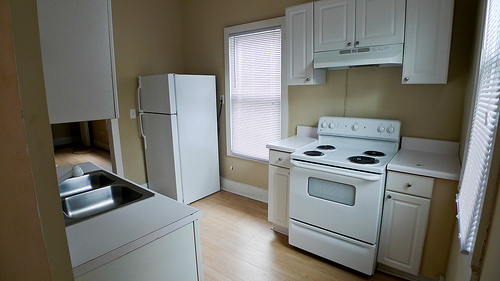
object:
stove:
[287, 116, 401, 276]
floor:
[186, 189, 406, 281]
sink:
[58, 169, 155, 226]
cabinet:
[284, 2, 326, 86]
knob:
[306, 78, 310, 81]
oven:
[288, 116, 401, 276]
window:
[308, 177, 356, 206]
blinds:
[224, 16, 289, 164]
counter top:
[265, 135, 317, 153]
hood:
[314, 44, 404, 71]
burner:
[349, 156, 380, 164]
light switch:
[129, 109, 136, 119]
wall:
[112, 0, 183, 186]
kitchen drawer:
[269, 150, 291, 169]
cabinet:
[313, 0, 406, 53]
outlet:
[220, 95, 225, 104]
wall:
[182, 0, 475, 190]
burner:
[303, 151, 324, 156]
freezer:
[136, 73, 220, 204]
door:
[137, 74, 176, 114]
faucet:
[57, 165, 84, 184]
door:
[137, 112, 183, 204]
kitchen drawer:
[385, 171, 435, 199]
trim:
[220, 177, 268, 204]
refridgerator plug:
[220, 100, 223, 102]